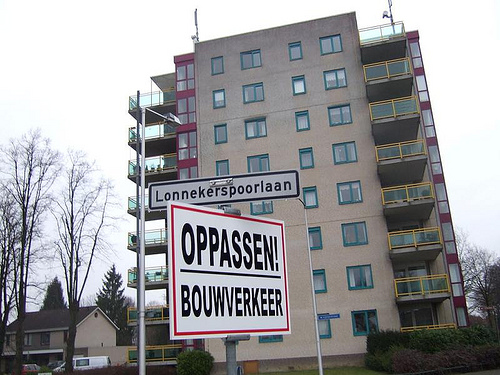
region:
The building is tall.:
[173, 12, 421, 363]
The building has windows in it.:
[160, 22, 427, 359]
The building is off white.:
[193, 10, 413, 360]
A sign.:
[164, 205, 296, 342]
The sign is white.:
[157, 197, 303, 346]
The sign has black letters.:
[161, 200, 303, 343]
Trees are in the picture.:
[1, 131, 102, 287]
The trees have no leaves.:
[3, 127, 98, 261]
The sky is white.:
[10, 34, 93, 99]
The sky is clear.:
[4, 25, 111, 115]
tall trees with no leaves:
[10, 147, 121, 271]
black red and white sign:
[115, 200, 307, 372]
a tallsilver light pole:
[64, 88, 186, 371]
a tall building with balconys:
[292, 75, 433, 357]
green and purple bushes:
[364, 320, 489, 372]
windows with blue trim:
[277, 165, 367, 367]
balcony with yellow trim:
[380, 105, 429, 310]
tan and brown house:
[1, 293, 128, 373]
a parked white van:
[55, 346, 120, 373]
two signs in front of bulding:
[139, 155, 350, 364]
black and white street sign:
[135, 167, 303, 207]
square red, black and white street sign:
[145, 206, 299, 344]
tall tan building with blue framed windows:
[124, 8, 472, 367]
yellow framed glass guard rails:
[337, 16, 464, 336]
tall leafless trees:
[5, 126, 115, 371]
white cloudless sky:
[7, 1, 498, 316]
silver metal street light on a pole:
[122, 99, 183, 372]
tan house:
[2, 301, 116, 373]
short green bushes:
[352, 326, 498, 373]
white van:
[47, 351, 115, 373]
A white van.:
[51, 354, 110, 373]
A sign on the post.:
[170, 205, 297, 341]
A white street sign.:
[140, 160, 302, 213]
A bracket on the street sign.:
[208, 172, 232, 189]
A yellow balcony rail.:
[392, 274, 451, 303]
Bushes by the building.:
[363, 322, 495, 373]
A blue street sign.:
[315, 309, 342, 326]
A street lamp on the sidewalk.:
[292, 186, 330, 373]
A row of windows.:
[285, 28, 355, 173]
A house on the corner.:
[5, 303, 120, 373]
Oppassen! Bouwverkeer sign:
[163, 200, 297, 342]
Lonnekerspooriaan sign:
[140, 178, 303, 203]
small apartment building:
[4, 290, 131, 353]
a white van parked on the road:
[55, 347, 115, 373]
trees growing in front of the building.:
[14, 152, 96, 286]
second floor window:
[336, 257, 384, 298]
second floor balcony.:
[389, 267, 458, 303]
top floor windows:
[200, 47, 345, 73]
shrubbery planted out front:
[357, 319, 489, 372]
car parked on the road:
[18, 357, 45, 373]